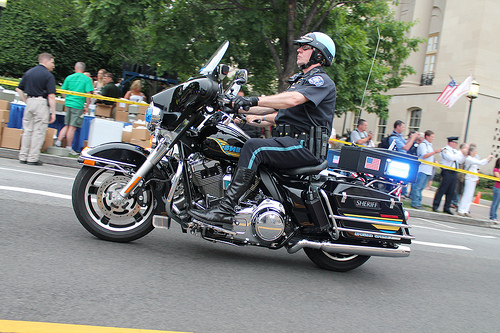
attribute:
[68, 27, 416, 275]
motorcycle — black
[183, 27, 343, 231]
officer — serious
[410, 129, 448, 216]
person — watching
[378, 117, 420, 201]
person — watching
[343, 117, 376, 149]
person — watching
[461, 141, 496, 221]
person — watching, preoccupied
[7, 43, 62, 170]
person — watching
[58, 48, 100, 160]
person — preoccupied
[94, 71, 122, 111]
person — preoccupied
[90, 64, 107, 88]
person — preoccupied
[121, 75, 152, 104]
person — preoccuopied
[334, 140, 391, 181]
garbage can — black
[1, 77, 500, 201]
tape — yellow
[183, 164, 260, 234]
boot — black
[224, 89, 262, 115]
glove — black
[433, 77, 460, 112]
american flag — flying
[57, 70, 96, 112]
shirt — green, black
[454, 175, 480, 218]
pants — white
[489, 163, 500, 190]
top — pink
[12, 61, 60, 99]
shirt — black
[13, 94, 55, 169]
pants — khaki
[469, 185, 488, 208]
cone — orange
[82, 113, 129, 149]
cardboard box — large, white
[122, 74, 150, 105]
woman — blonde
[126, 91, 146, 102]
tank top — white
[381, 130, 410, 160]
shirt — blue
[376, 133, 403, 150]
backpack — black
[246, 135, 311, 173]
strip — blue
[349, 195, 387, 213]
word — sheriff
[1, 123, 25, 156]
box — brown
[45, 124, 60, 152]
box — brown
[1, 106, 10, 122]
box — brown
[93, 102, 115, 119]
box — brown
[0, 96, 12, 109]
box — brown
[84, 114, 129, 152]
box — white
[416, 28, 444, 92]
window — tan